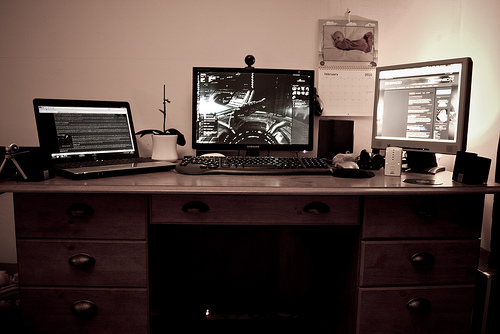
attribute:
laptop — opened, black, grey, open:
[33, 97, 175, 183]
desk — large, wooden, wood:
[2, 156, 498, 333]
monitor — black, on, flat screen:
[191, 66, 315, 151]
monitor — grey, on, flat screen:
[372, 57, 474, 157]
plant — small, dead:
[134, 84, 187, 147]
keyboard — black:
[175, 155, 332, 177]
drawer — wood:
[13, 192, 149, 241]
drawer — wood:
[15, 239, 148, 287]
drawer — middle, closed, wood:
[149, 195, 365, 226]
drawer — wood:
[362, 195, 484, 239]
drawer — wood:
[359, 239, 480, 284]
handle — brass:
[65, 202, 95, 221]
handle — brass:
[67, 253, 96, 271]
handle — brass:
[179, 199, 212, 215]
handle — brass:
[414, 201, 442, 220]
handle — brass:
[409, 250, 434, 268]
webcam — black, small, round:
[244, 54, 256, 69]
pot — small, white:
[151, 134, 179, 162]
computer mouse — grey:
[336, 160, 360, 169]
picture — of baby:
[324, 23, 376, 61]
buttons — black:
[181, 158, 327, 170]